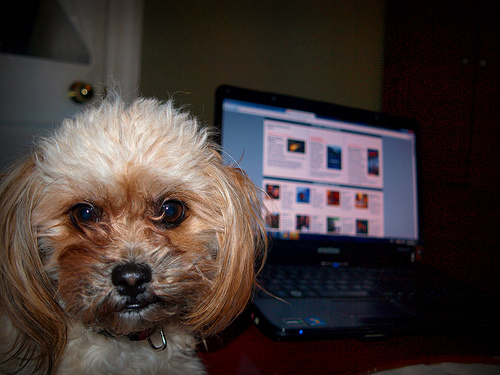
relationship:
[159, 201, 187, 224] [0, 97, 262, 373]
eye of dog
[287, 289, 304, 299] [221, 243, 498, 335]
key on keyboard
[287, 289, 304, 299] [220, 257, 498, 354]
key on keyboard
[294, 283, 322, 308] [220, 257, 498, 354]
key on keyboard